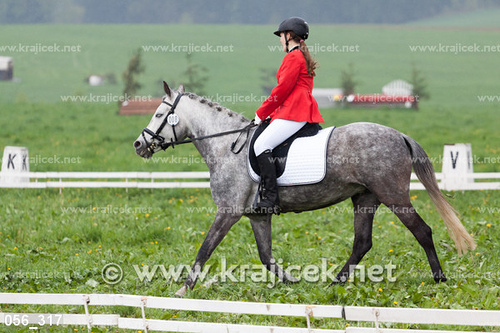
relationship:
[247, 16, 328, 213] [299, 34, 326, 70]
woman has hair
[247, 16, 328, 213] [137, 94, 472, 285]
woman of horse